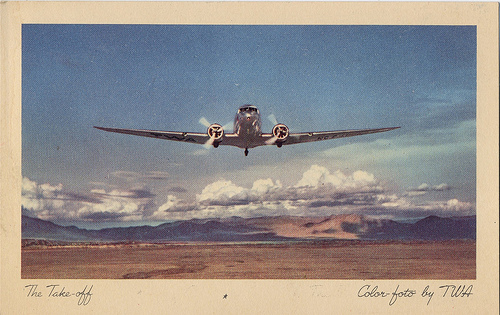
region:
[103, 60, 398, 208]
plane in the air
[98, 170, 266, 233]
clouds in the sky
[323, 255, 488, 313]
words in bottom right corner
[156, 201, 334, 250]
hills in the distance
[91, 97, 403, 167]
plane flying through air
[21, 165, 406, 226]
clouds across a sky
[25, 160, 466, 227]
clouds scattered across horizon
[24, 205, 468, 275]
a field with mountains behind them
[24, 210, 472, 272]
mountaisn standing above a prarie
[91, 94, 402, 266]
plane flying over a field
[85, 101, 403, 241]
an airplane passes over mountains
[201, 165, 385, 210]
a logn white cloud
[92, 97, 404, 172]
a 20th century plane in the sky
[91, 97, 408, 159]
A silver plane flying in the sky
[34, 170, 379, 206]
Puffy clouds in the blue sky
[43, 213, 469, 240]
Mountains in the background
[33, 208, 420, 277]
Mountains meet the barren landscape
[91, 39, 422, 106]
Blue skies are seen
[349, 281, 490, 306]
authorship of a photo is TWA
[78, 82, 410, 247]
A plane flying over the mountains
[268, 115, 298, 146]
One of the props of a plane spinning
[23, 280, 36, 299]
black hand written letter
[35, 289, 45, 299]
black hand written letter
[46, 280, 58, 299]
black hand written letter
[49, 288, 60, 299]
black hand written letter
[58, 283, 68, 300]
black hand written letter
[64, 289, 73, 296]
black hand written letter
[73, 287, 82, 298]
black hand written letter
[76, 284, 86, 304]
black hand written letter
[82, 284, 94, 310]
black hand written letter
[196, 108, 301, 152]
Propellers on front of airplane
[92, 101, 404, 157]
Plane taking off into the air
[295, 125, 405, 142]
Wing on side of plane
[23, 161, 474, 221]
Low clouds in the background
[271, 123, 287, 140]
Engine on wing of plane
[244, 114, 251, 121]
Nose on front of plane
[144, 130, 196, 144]
Logo under wing of plane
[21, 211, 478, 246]
Mountain range in the background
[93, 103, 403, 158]
Flight of old prop rotor plane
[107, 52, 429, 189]
plane in the air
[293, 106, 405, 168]
wing of the plane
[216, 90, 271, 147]
front of the plane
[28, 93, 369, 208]
Airplane flying in the sky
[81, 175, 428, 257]
Mountains in the background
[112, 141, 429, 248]
Big fluffy white clouds and sky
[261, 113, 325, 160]
A airplane propeller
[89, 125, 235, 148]
Airplane wing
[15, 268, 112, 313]
Name of the photo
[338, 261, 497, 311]
The name of who took the photo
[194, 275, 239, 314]
A star draw on the photo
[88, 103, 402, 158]
plane flying in the air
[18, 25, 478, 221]
clouds in the sky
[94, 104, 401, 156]
plane has set of wings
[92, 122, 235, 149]
TWA on bottom of wing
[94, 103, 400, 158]
propellers turning on plane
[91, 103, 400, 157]
plane is silver color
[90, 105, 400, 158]
landing wheel on the plane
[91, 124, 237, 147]
Silver wing with TWA on the bottom.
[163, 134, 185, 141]
A large black W on a wing bottom.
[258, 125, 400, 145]
Silver plane wing with smaller writing.